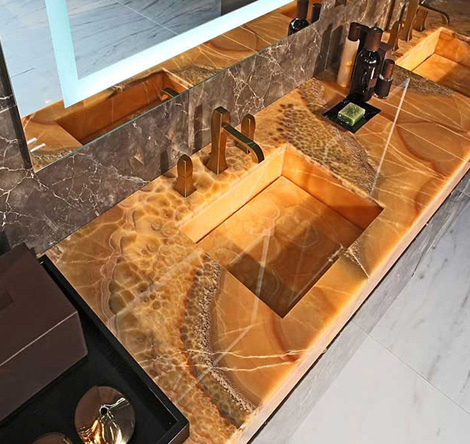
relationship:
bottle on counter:
[345, 25, 381, 100] [41, 0, 468, 443]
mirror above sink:
[0, 0, 356, 176] [173, 106, 390, 315]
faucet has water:
[204, 105, 264, 175] [255, 151, 266, 171]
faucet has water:
[173, 104, 264, 200] [255, 151, 266, 171]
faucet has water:
[400, 0, 450, 42] [255, 151, 266, 171]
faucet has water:
[396, 0, 449, 42] [255, 151, 266, 171]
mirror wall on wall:
[2, 0, 338, 156] [3, 2, 318, 166]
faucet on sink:
[204, 105, 264, 175] [166, 134, 387, 327]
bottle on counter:
[347, 26, 382, 102] [71, 10, 458, 425]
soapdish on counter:
[324, 90, 381, 134] [80, 82, 465, 443]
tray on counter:
[2, 224, 228, 438] [57, 69, 468, 433]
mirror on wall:
[27, 22, 353, 98] [0, 1, 429, 258]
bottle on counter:
[329, 20, 365, 89] [41, 0, 468, 443]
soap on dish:
[337, 102, 365, 126] [309, 90, 388, 143]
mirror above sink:
[0, 0, 356, 176] [160, 113, 404, 321]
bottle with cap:
[342, 18, 380, 88] [350, 24, 363, 41]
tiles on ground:
[251, 170, 467, 441] [245, 167, 468, 442]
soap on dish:
[337, 102, 365, 126] [322, 94, 382, 134]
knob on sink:
[242, 111, 255, 151] [173, 106, 390, 315]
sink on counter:
[173, 106, 390, 315] [41, 0, 468, 443]